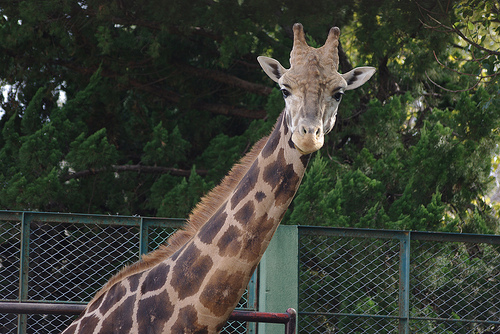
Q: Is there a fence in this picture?
A: Yes, there is a fence.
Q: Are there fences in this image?
A: Yes, there is a fence.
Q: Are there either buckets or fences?
A: Yes, there is a fence.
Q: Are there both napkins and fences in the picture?
A: No, there is a fence but no napkins.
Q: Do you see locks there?
A: No, there are no locks.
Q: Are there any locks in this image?
A: No, there are no locks.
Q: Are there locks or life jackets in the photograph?
A: No, there are no locks or life jackets.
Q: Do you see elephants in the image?
A: No, there are no elephants.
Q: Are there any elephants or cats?
A: No, there are no elephants or cats.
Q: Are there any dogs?
A: No, there are no dogs.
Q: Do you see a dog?
A: No, there are no dogs.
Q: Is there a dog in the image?
A: No, there are no dogs.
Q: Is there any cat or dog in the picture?
A: No, there are no dogs or cats.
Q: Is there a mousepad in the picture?
A: No, there are no mouse pads.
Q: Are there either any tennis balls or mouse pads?
A: No, there are no mouse pads or tennis balls.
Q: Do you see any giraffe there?
A: Yes, there is a giraffe.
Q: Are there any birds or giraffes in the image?
A: Yes, there is a giraffe.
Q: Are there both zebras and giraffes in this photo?
A: No, there is a giraffe but no zebras.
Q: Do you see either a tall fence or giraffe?
A: Yes, there is a tall giraffe.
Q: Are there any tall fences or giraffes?
A: Yes, there is a tall giraffe.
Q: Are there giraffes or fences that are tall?
A: Yes, the giraffe is tall.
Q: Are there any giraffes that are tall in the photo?
A: Yes, there is a tall giraffe.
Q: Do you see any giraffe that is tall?
A: Yes, there is a giraffe that is tall.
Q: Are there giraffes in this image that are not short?
A: Yes, there is a tall giraffe.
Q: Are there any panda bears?
A: No, there are no panda bears.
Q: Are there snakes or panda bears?
A: No, there are no panda bears or snakes.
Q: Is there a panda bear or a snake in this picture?
A: No, there are no panda bears or snakes.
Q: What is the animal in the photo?
A: The animal is a giraffe.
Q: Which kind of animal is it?
A: The animal is a giraffe.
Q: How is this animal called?
A: This is a giraffe.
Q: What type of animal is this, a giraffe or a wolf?
A: This is a giraffe.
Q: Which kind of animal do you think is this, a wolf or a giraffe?
A: This is a giraffe.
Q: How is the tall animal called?
A: The animal is a giraffe.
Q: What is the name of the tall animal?
A: The animal is a giraffe.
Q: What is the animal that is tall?
A: The animal is a giraffe.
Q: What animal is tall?
A: The animal is a giraffe.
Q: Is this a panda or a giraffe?
A: This is a giraffe.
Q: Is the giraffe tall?
A: Yes, the giraffe is tall.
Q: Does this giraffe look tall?
A: Yes, the giraffe is tall.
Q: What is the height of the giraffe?
A: The giraffe is tall.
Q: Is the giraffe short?
A: No, the giraffe is tall.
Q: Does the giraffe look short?
A: No, the giraffe is tall.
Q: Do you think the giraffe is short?
A: No, the giraffe is tall.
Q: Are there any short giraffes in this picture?
A: No, there is a giraffe but it is tall.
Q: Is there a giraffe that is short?
A: No, there is a giraffe but it is tall.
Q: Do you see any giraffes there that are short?
A: No, there is a giraffe but it is tall.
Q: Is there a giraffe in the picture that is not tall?
A: No, there is a giraffe but it is tall.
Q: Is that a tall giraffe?
A: Yes, that is a tall giraffe.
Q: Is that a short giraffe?
A: No, that is a tall giraffe.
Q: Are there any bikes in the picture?
A: No, there are no bikes.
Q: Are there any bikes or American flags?
A: No, there are no bikes or American flags.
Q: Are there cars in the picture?
A: No, there are no cars.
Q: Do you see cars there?
A: No, there are no cars.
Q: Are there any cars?
A: No, there are no cars.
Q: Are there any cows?
A: No, there are no cows.